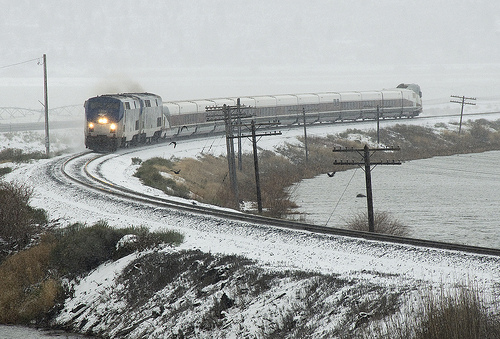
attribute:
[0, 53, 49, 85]
wire — electrical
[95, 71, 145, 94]
exhaust — faint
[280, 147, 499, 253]
water — open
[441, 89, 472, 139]
pole — utility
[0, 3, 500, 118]
sky — gray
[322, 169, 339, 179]
bird — flying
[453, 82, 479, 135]
pole — utility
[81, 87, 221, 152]
locomotive — blue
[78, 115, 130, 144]
locomotive headlights — on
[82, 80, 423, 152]
train — white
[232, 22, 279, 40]
sky — blue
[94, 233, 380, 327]
snow — hill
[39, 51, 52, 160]
utility pole — distant 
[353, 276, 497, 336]
weeds — tall, brown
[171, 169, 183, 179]
bird — flying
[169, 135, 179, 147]
bird — flying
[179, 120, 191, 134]
bird — flying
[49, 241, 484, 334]
hill — covered